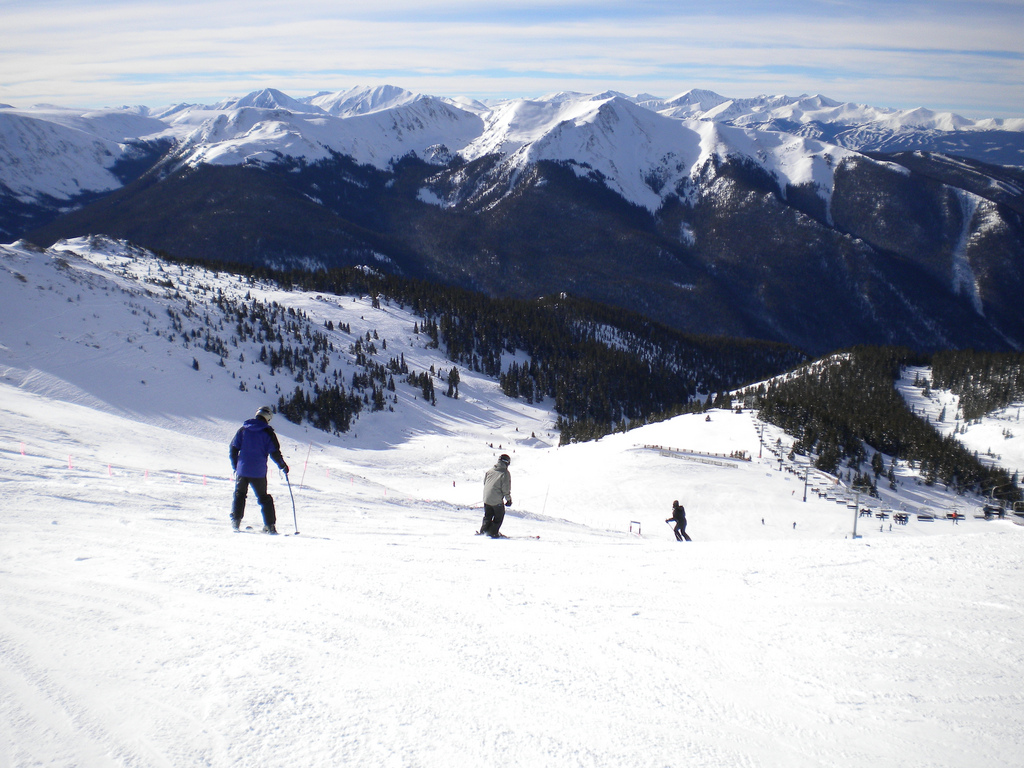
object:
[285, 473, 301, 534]
ski pole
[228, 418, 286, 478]
coat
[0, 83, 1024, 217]
snow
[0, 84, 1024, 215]
cap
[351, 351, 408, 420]
trees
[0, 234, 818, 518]
hill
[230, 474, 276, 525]
legs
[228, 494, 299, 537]
skis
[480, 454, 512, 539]
man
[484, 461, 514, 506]
coat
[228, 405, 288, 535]
man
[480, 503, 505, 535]
pants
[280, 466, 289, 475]
hand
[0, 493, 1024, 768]
hill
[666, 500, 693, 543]
person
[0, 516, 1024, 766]
ski slope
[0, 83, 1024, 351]
mountain range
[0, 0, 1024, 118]
sky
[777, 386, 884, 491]
tree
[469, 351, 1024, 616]
hill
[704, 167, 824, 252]
trees